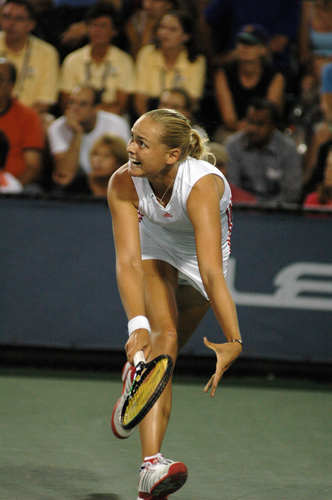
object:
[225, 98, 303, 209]
spectator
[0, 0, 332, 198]
stands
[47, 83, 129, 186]
spectator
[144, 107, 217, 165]
hair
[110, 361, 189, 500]
shoes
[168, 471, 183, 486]
red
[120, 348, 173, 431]
racket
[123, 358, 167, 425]
yellow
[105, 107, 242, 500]
woman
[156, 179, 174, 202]
necklace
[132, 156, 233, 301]
clothes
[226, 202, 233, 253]
stripes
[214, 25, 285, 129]
audience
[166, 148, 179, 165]
ear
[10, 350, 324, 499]
court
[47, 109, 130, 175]
shirt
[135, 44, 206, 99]
shirt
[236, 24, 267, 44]
cap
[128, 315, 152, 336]
band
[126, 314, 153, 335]
wrist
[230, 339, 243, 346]
watch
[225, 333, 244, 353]
wrist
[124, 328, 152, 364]
hand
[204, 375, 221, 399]
fingers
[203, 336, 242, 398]
hand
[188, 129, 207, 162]
ponytail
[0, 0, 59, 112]
spectators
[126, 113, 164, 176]
face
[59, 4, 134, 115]
fan